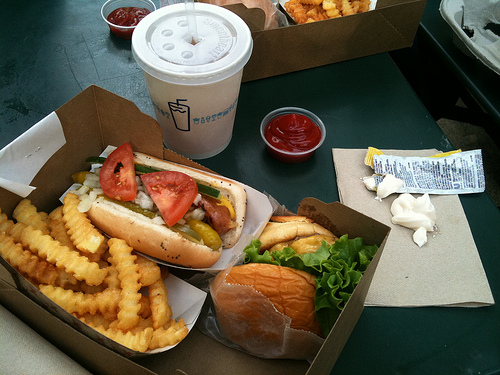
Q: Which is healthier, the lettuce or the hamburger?
A: The lettuce is healthier than the hamburger.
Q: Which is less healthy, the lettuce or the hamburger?
A: The hamburger is less healthy than the lettuce.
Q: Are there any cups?
A: Yes, there is a cup.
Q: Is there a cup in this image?
A: Yes, there is a cup.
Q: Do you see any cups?
A: Yes, there is a cup.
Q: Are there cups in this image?
A: Yes, there is a cup.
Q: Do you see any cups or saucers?
A: Yes, there is a cup.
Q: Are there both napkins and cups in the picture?
A: Yes, there are both a cup and a napkin.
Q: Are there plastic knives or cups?
A: Yes, there is a plastic cup.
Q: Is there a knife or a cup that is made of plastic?
A: Yes, the cup is made of plastic.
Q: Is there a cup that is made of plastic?
A: Yes, there is a cup that is made of plastic.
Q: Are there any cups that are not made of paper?
A: Yes, there is a cup that is made of plastic.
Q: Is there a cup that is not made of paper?
A: Yes, there is a cup that is made of plastic.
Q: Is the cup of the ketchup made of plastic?
A: Yes, the cup is made of plastic.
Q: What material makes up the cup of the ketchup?
A: The cup is made of plastic.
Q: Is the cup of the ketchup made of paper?
A: No, the cup is made of plastic.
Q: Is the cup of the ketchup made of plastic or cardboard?
A: The cup is made of plastic.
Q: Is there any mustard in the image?
A: Yes, there is mustard.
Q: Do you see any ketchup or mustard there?
A: Yes, there is mustard.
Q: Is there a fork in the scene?
A: No, there are no forks.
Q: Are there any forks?
A: No, there are no forks.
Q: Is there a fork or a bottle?
A: No, there are no forks or bottles.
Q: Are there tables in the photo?
A: Yes, there is a table.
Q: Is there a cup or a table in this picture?
A: Yes, there is a table.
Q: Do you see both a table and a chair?
A: No, there is a table but no chairs.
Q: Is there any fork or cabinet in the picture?
A: No, there are no forks or cabinets.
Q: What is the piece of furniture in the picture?
A: The piece of furniture is a table.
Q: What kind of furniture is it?
A: The piece of furniture is a table.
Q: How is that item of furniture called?
A: This is a table.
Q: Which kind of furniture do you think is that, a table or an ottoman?
A: This is a table.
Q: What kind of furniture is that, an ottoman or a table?
A: This is a table.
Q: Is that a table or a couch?
A: That is a table.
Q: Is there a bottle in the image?
A: No, there are no bottles.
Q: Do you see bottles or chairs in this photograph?
A: No, there are no bottles or chairs.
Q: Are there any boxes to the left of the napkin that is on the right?
A: Yes, there is a box to the left of the napkin.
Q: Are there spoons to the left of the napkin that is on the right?
A: No, there is a box to the left of the napkin.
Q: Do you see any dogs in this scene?
A: Yes, there is a dog.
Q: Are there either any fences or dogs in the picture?
A: Yes, there is a dog.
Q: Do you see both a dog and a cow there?
A: No, there is a dog but no cows.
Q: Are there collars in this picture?
A: No, there are no collars.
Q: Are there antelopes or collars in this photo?
A: No, there are no collars or antelopes.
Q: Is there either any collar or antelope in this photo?
A: No, there are no collars or antelopes.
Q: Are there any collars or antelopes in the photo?
A: No, there are no collars or antelopes.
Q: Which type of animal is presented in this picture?
A: The animal is a dog.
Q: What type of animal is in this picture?
A: The animal is a dog.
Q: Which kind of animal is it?
A: The animal is a dog.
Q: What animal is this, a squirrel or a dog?
A: This is a dog.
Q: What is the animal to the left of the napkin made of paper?
A: The animal is a dog.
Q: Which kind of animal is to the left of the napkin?
A: The animal is a dog.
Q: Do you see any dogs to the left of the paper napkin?
A: Yes, there is a dog to the left of the napkin.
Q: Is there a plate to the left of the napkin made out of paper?
A: No, there is a dog to the left of the napkin.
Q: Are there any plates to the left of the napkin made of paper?
A: No, there is a dog to the left of the napkin.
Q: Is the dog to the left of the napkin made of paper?
A: Yes, the dog is to the left of the napkin.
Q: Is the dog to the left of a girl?
A: No, the dog is to the left of the napkin.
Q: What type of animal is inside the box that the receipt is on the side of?
A: The animal is a dog.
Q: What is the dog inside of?
A: The dog is inside the box.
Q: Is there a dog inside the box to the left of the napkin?
A: Yes, there is a dog inside the box.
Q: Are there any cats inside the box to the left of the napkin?
A: No, there is a dog inside the box.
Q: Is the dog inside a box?
A: Yes, the dog is inside a box.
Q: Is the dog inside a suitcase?
A: No, the dog is inside a box.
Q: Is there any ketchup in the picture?
A: Yes, there is ketchup.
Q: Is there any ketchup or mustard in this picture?
A: Yes, there is ketchup.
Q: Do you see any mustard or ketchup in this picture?
A: Yes, there is ketchup.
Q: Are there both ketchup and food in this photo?
A: Yes, there are both ketchup and food.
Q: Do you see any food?
A: Yes, there is food.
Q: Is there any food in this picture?
A: Yes, there is food.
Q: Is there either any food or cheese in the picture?
A: Yes, there is food.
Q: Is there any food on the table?
A: Yes, there is food on the table.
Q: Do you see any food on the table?
A: Yes, there is food on the table.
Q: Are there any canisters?
A: No, there are no canisters.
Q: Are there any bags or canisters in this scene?
A: No, there are no canisters or bags.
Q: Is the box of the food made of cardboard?
A: Yes, the box is made of cardboard.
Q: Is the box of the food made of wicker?
A: No, the box is made of cardboard.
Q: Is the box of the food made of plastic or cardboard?
A: The box is made of cardboard.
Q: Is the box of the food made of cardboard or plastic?
A: The box is made of cardboard.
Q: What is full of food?
A: The box is full of food.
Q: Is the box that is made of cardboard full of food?
A: Yes, the box is full of food.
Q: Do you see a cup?
A: Yes, there is a cup.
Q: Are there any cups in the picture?
A: Yes, there is a cup.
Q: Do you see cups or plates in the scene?
A: Yes, there is a cup.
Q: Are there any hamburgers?
A: Yes, there is a hamburger.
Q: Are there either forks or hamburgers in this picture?
A: Yes, there is a hamburger.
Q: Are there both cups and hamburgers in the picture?
A: Yes, there are both a hamburger and a cup.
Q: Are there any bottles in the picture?
A: No, there are no bottles.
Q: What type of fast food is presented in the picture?
A: The fast food is a hamburger.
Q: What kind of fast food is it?
A: The food is a hamburger.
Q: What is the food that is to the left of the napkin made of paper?
A: The food is a hamburger.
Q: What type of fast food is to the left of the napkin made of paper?
A: The food is a hamburger.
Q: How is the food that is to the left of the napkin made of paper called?
A: The food is a hamburger.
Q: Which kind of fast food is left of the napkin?
A: The food is a hamburger.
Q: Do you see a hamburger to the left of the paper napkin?
A: Yes, there is a hamburger to the left of the napkin.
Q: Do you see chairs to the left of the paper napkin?
A: No, there is a hamburger to the left of the napkin.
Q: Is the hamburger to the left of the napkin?
A: Yes, the hamburger is to the left of the napkin.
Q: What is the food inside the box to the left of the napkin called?
A: The food is a hamburger.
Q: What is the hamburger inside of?
A: The hamburger is inside the box.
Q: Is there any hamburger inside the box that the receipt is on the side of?
A: Yes, there is a hamburger inside the box.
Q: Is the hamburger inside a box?
A: Yes, the hamburger is inside a box.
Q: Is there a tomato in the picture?
A: Yes, there is a tomato.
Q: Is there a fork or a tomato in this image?
A: Yes, there is a tomato.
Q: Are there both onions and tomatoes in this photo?
A: Yes, there are both a tomato and an onion.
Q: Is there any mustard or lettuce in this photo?
A: Yes, there is mustard.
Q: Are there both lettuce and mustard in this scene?
A: Yes, there are both mustard and lettuce.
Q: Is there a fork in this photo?
A: No, there are no forks.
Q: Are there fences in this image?
A: No, there are no fences.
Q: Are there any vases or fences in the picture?
A: No, there are no fences or vases.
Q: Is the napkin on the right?
A: Yes, the napkin is on the right of the image.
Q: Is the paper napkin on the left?
A: No, the napkin is on the right of the image.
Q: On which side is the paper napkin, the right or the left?
A: The napkin is on the right of the image.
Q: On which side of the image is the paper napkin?
A: The napkin is on the right of the image.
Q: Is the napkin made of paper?
A: Yes, the napkin is made of paper.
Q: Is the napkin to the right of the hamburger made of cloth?
A: No, the napkin is made of paper.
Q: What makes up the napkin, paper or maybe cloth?
A: The napkin is made of paper.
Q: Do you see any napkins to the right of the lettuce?
A: Yes, there is a napkin to the right of the lettuce.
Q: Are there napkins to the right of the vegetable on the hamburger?
A: Yes, there is a napkin to the right of the lettuce.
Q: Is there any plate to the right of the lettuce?
A: No, there is a napkin to the right of the lettuce.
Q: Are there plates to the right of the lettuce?
A: No, there is a napkin to the right of the lettuce.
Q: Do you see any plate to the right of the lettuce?
A: No, there is a napkin to the right of the lettuce.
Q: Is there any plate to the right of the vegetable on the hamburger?
A: No, there is a napkin to the right of the lettuce.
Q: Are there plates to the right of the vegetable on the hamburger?
A: No, there is a napkin to the right of the lettuce.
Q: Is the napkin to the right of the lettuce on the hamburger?
A: Yes, the napkin is to the right of the lettuce.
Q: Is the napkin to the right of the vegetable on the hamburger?
A: Yes, the napkin is to the right of the lettuce.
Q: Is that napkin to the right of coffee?
A: No, the napkin is to the right of the lettuce.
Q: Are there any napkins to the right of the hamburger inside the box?
A: Yes, there is a napkin to the right of the hamburger.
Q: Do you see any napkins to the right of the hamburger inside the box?
A: Yes, there is a napkin to the right of the hamburger.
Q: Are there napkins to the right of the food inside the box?
A: Yes, there is a napkin to the right of the hamburger.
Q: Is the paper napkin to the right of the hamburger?
A: Yes, the napkin is to the right of the hamburger.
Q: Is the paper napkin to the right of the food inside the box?
A: Yes, the napkin is to the right of the hamburger.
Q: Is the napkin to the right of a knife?
A: No, the napkin is to the right of the hamburger.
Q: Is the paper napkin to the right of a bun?
A: Yes, the napkin is to the right of a bun.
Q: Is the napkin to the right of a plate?
A: No, the napkin is to the right of a bun.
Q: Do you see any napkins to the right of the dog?
A: Yes, there is a napkin to the right of the dog.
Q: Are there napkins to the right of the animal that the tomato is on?
A: Yes, there is a napkin to the right of the dog.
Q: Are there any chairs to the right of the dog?
A: No, there is a napkin to the right of the dog.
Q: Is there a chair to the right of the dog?
A: No, there is a napkin to the right of the dog.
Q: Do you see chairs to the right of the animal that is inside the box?
A: No, there is a napkin to the right of the dog.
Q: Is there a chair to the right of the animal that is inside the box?
A: No, there is a napkin to the right of the dog.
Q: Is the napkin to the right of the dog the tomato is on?
A: Yes, the napkin is to the right of the dog.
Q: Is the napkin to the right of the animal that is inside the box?
A: Yes, the napkin is to the right of the dog.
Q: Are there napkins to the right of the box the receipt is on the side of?
A: Yes, there is a napkin to the right of the box.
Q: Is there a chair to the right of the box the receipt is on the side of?
A: No, there is a napkin to the right of the box.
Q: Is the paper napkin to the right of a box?
A: Yes, the napkin is to the right of a box.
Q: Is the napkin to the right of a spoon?
A: No, the napkin is to the right of a box.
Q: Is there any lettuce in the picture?
A: Yes, there is lettuce.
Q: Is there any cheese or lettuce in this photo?
A: Yes, there is lettuce.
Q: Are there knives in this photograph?
A: No, there are no knives.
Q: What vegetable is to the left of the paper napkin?
A: The vegetable is lettuce.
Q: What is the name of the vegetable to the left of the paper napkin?
A: The vegetable is lettuce.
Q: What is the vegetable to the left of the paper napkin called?
A: The vegetable is lettuce.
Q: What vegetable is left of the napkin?
A: The vegetable is lettuce.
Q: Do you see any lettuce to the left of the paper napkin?
A: Yes, there is lettuce to the left of the napkin.